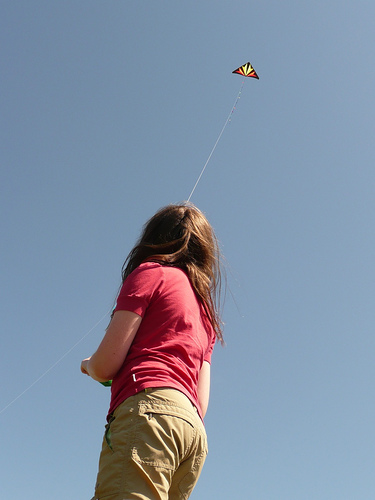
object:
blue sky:
[0, 0, 375, 499]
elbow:
[88, 349, 119, 383]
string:
[186, 81, 245, 205]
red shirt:
[106, 262, 213, 423]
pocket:
[131, 401, 194, 470]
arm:
[89, 265, 153, 381]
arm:
[197, 343, 211, 418]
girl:
[80, 202, 226, 500]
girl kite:
[231, 63, 259, 80]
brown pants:
[93, 388, 208, 500]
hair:
[104, 199, 241, 348]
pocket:
[104, 409, 115, 454]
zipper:
[143, 411, 195, 429]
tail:
[228, 77, 248, 125]